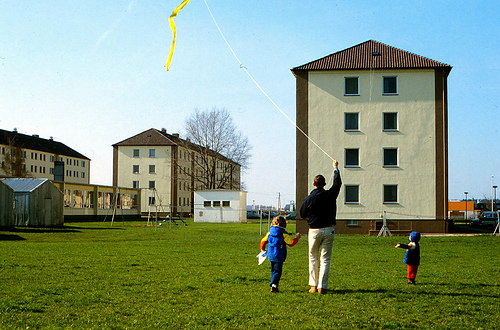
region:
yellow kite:
[149, 8, 204, 75]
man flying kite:
[273, 131, 348, 308]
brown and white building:
[281, 32, 443, 176]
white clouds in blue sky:
[12, 13, 41, 43]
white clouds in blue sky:
[64, 13, 114, 40]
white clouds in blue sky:
[4, 54, 54, 94]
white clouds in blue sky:
[67, 70, 94, 108]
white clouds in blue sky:
[78, 41, 138, 104]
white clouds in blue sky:
[189, 20, 242, 82]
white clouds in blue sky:
[241, 32, 272, 83]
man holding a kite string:
[292, 152, 349, 302]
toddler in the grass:
[393, 228, 424, 287]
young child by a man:
[252, 208, 305, 294]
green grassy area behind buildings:
[1, 212, 498, 329]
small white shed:
[189, 181, 253, 228]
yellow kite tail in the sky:
[164, 0, 191, 72]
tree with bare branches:
[177, 103, 254, 211]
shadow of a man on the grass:
[309, 283, 499, 310]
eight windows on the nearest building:
[336, 73, 404, 210]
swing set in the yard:
[103, 180, 168, 227]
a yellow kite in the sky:
[143, 6, 233, 77]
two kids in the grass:
[232, 196, 469, 321]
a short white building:
[180, 184, 270, 242]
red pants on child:
[391, 259, 456, 289]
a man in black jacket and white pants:
[286, 153, 355, 314]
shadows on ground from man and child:
[314, 268, 499, 317]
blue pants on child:
[251, 253, 316, 290]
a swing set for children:
[106, 180, 199, 250]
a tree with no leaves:
[161, 94, 256, 248]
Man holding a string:
[300, 129, 341, 300]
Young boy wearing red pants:
[395, 231, 425, 281]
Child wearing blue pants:
[247, 215, 302, 300]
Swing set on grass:
[102, 181, 189, 238]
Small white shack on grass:
[186, 185, 257, 232]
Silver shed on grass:
[5, 176, 71, 235]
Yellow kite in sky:
[147, 0, 194, 78]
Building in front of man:
[285, 31, 455, 238]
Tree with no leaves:
[178, 111, 248, 214]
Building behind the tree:
[110, 132, 251, 228]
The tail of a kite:
[171, 18, 174, 28]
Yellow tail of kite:
[170, 22, 174, 34]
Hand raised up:
[333, 160, 338, 166]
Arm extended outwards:
[395, 243, 407, 248]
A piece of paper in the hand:
[260, 254, 264, 261]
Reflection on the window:
[78, 193, 82, 202]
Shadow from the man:
[333, 290, 354, 293]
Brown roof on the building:
[359, 50, 372, 64]